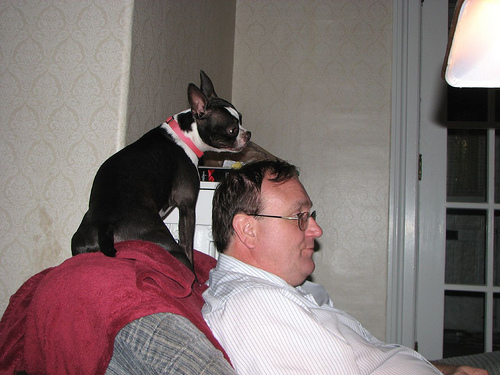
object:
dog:
[68, 67, 253, 290]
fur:
[68, 72, 255, 251]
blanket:
[0, 238, 234, 373]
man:
[200, 160, 490, 374]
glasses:
[237, 200, 317, 227]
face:
[255, 169, 322, 288]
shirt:
[201, 251, 441, 374]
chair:
[20, 239, 251, 374]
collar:
[164, 115, 205, 159]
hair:
[208, 160, 301, 254]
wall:
[1, 2, 389, 342]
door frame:
[386, 0, 499, 363]